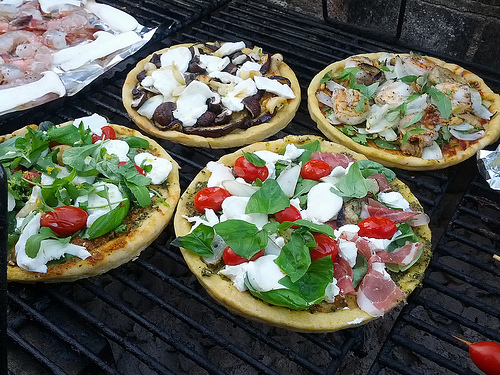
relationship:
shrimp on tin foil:
[0, 1, 88, 83] [0, 1, 159, 117]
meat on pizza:
[334, 229, 418, 317] [174, 134, 433, 332]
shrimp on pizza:
[332, 87, 370, 123] [308, 50, 499, 169]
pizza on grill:
[308, 50, 499, 169] [1, 1, 499, 373]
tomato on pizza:
[195, 186, 231, 210] [174, 134, 433, 332]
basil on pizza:
[216, 218, 276, 259] [174, 134, 433, 332]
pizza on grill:
[174, 134, 433, 332] [1, 1, 499, 373]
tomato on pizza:
[235, 156, 269, 183] [174, 134, 433, 332]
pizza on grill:
[122, 41, 303, 150] [1, 1, 499, 373]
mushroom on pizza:
[154, 100, 179, 132] [122, 41, 303, 150]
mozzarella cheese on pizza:
[304, 180, 344, 222] [174, 134, 433, 332]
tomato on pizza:
[356, 216, 397, 239] [174, 134, 433, 332]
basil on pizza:
[272, 232, 317, 283] [174, 134, 433, 332]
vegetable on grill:
[455, 330, 499, 374] [1, 1, 499, 373]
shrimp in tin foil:
[0, 1, 88, 83] [0, 1, 159, 117]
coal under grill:
[107, 284, 223, 372] [1, 1, 499, 373]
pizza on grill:
[0, 112, 181, 285] [1, 1, 499, 373]